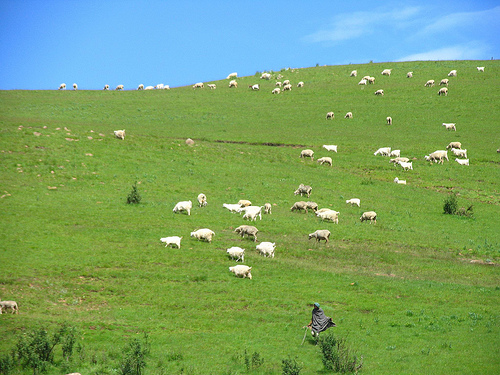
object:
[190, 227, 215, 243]
sheep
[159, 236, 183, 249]
sheep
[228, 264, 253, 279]
sheep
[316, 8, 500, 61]
clouds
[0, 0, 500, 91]
sky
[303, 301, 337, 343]
person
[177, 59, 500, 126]
hill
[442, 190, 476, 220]
bush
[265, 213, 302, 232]
grass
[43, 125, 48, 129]
rocks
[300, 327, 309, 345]
cane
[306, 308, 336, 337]
coverall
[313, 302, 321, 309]
cap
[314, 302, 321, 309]
head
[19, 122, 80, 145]
patches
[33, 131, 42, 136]
dirt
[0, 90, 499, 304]
field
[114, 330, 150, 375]
shrubs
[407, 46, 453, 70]
hillside